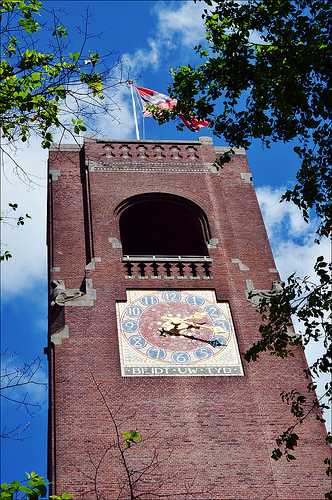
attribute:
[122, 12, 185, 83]
sky — blue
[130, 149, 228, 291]
building — brick, brown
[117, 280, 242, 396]
clock — white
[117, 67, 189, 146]
flag — waving, red